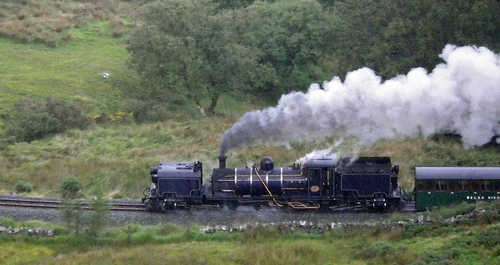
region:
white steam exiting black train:
[215, 40, 495, 160]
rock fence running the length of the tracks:
[8, 200, 498, 239]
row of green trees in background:
[31, 10, 495, 132]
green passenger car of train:
[408, 162, 498, 214]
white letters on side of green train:
[466, 194, 498, 203]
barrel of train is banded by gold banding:
[216, 161, 309, 197]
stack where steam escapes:
[214, 155, 232, 168]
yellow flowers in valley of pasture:
[85, 106, 137, 126]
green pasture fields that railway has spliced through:
[5, 5, 499, 256]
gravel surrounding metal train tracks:
[6, 197, 421, 217]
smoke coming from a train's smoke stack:
[192, 43, 497, 170]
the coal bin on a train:
[339, 159, 396, 202]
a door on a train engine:
[304, 169, 326, 199]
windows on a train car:
[435, 180, 493, 191]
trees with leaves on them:
[368, 13, 450, 43]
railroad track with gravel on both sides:
[10, 193, 64, 214]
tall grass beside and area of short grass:
[10, 11, 73, 52]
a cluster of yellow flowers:
[95, 108, 126, 123]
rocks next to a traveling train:
[197, 216, 349, 236]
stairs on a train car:
[404, 195, 419, 212]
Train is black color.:
[131, 135, 473, 222]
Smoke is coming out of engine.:
[206, 93, 442, 171]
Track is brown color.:
[7, 188, 143, 233]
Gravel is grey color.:
[1, 188, 131, 225]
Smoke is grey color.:
[218, 80, 445, 164]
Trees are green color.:
[70, 22, 240, 102]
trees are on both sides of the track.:
[35, 25, 365, 260]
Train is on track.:
[47, 144, 265, 240]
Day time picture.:
[21, 32, 496, 252]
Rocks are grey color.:
[190, 215, 409, 242]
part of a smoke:
[269, 105, 299, 130]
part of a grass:
[238, 243, 263, 260]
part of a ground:
[285, 219, 309, 251]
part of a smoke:
[315, 133, 355, 193]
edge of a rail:
[329, 200, 350, 223]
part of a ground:
[358, 225, 379, 244]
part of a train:
[306, 193, 336, 239]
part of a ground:
[374, 231, 393, 262]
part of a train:
[326, 164, 345, 189]